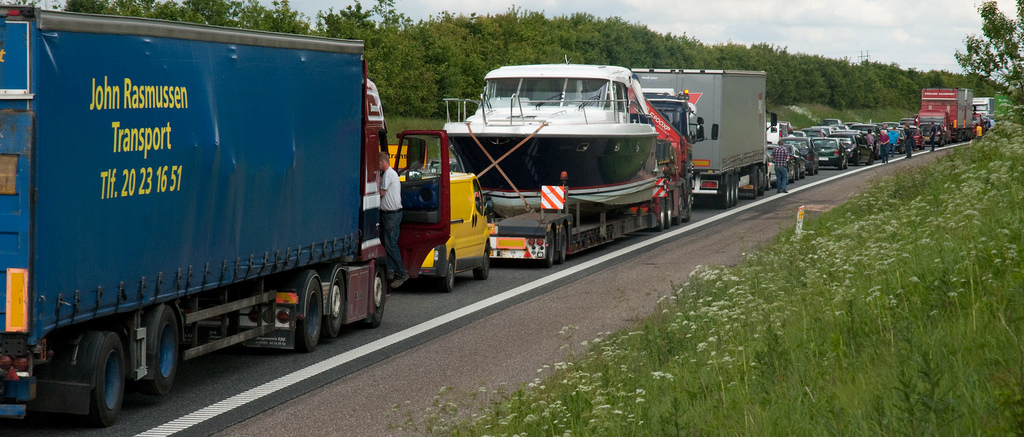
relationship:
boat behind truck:
[716, 38, 856, 210] [629, 70, 784, 191]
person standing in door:
[369, 137, 405, 268] [369, 123, 459, 269]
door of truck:
[369, 123, 459, 269] [21, 14, 464, 318]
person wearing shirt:
[380, 152, 408, 288] [376, 169, 409, 205]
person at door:
[380, 152, 408, 288] [380, 130, 456, 276]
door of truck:
[380, 130, 456, 276] [11, 5, 479, 334]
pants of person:
[381, 212, 411, 270] [380, 152, 408, 288]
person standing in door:
[380, 152, 408, 288] [380, 130, 456, 276]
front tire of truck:
[348, 250, 403, 323] [2, 1, 467, 368]